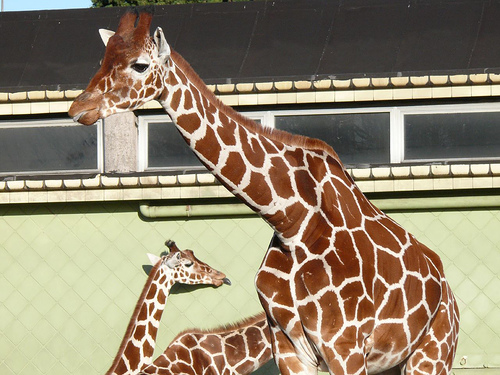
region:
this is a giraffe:
[136, 23, 416, 202]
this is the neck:
[166, 83, 263, 182]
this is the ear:
[148, 28, 168, 62]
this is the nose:
[70, 92, 83, 119]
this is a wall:
[38, 146, 125, 348]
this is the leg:
[312, 345, 343, 371]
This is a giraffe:
[79, 213, 243, 374]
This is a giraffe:
[74, 7, 431, 364]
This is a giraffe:
[115, 234, 250, 367]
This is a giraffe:
[144, 284, 279, 374]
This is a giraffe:
[101, 213, 226, 374]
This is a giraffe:
[94, 230, 261, 374]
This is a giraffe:
[54, 4, 379, 231]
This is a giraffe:
[54, 0, 391, 247]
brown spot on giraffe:
[157, 85, 170, 106]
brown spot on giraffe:
[169, 85, 181, 112]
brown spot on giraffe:
[166, 70, 181, 87]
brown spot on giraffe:
[175, 61, 187, 88]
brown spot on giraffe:
[176, 112, 205, 134]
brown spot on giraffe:
[192, 123, 223, 165]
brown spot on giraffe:
[219, 151, 249, 185]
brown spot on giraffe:
[242, 165, 272, 206]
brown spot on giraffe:
[266, 153, 294, 202]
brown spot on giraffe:
[292, 165, 320, 209]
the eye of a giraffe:
[124, 51, 156, 79]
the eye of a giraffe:
[181, 258, 194, 270]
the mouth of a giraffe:
[63, 92, 108, 127]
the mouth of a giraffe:
[201, 264, 231, 290]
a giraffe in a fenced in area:
[65, 4, 462, 374]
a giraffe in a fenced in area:
[98, 238, 230, 373]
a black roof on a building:
[0, 3, 497, 105]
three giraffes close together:
[55, 6, 459, 373]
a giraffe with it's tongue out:
[93, 239, 230, 374]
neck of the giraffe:
[178, 102, 226, 151]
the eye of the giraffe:
[181, 258, 196, 271]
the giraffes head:
[67, 20, 157, 125]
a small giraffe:
[138, 239, 229, 299]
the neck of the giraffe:
[133, 314, 170, 357]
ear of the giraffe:
[146, 27, 171, 56]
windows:
[411, 123, 484, 153]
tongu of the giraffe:
[72, 112, 88, 121]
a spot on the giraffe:
[313, 190, 348, 241]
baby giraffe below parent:
[88, 241, 243, 372]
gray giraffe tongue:
[217, 272, 232, 288]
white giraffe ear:
[167, 248, 182, 269]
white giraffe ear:
[142, 246, 168, 268]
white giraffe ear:
[150, 20, 174, 64]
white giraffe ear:
[90, 24, 120, 49]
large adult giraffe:
[69, 10, 470, 369]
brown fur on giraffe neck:
[178, 63, 351, 162]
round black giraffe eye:
[128, 55, 152, 78]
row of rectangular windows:
[6, 100, 498, 179]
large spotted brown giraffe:
[69, 11, 463, 373]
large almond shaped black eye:
[126, 59, 151, 73]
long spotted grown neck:
[160, 46, 316, 238]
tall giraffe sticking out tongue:
[81, 239, 233, 374]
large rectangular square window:
[400, 106, 499, 162]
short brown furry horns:
[113, 12, 155, 37]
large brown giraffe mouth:
[68, 97, 105, 127]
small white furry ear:
[151, 23, 170, 58]